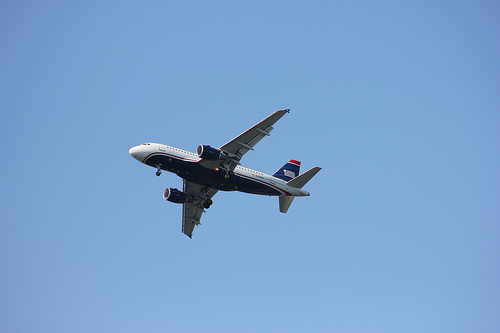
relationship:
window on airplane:
[147, 143, 151, 148] [125, 107, 324, 241]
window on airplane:
[142, 142, 146, 145] [125, 107, 324, 241]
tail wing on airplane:
[277, 193, 297, 214] [125, 107, 324, 241]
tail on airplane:
[285, 166, 325, 189] [125, 107, 324, 241]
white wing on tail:
[212, 103, 293, 163] [285, 166, 325, 189]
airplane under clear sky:
[125, 107, 324, 241] [2, 0, 497, 331]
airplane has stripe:
[125, 107, 324, 241] [156, 153, 276, 194]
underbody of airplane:
[148, 152, 282, 197] [125, 107, 324, 241]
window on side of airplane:
[162, 146, 176, 149] [125, 107, 324, 241]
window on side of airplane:
[254, 168, 264, 175] [125, 107, 324, 241]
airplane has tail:
[118, 102, 322, 242] [273, 152, 320, 217]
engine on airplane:
[163, 187, 200, 206] [125, 107, 324, 241]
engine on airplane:
[194, 141, 225, 162] [125, 107, 324, 241]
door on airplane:
[268, 175, 280, 188] [125, 107, 324, 241]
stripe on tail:
[284, 157, 302, 169] [273, 155, 301, 180]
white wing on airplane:
[212, 103, 293, 163] [118, 102, 322, 242]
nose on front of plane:
[122, 143, 150, 160] [119, 102, 325, 237]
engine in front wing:
[194, 141, 225, 162] [199, 107, 290, 173]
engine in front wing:
[163, 187, 200, 206] [182, 176, 210, 238]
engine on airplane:
[194, 141, 225, 162] [118, 102, 322, 242]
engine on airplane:
[163, 187, 200, 206] [118, 102, 322, 242]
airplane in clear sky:
[125, 107, 324, 241] [0, 0, 498, 331]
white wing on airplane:
[169, 177, 221, 241] [125, 107, 324, 241]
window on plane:
[162, 146, 176, 149] [102, 79, 359, 289]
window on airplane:
[261, 171, 264, 175] [125, 107, 324, 241]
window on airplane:
[253, 168, 255, 173] [125, 107, 324, 241]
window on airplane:
[239, 164, 244, 169] [125, 107, 324, 241]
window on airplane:
[177, 146, 182, 152] [125, 107, 324, 241]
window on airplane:
[239, 162, 246, 174] [125, 107, 324, 241]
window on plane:
[254, 168, 264, 175] [129, 102, 349, 230]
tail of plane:
[285, 166, 325, 189] [102, 79, 345, 248]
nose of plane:
[128, 144, 144, 159] [83, 95, 378, 215]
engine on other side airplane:
[161, 185, 198, 208] [125, 107, 324, 241]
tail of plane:
[262, 158, 324, 213] [84, 113, 359, 261]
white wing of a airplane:
[212, 103, 293, 163] [125, 107, 324, 241]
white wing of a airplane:
[212, 103, 293, 163] [91, 72, 376, 267]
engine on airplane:
[194, 141, 225, 162] [91, 72, 376, 267]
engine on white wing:
[194, 141, 225, 162] [212, 103, 293, 163]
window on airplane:
[186, 150, 191, 155] [125, 107, 324, 241]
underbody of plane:
[148, 152, 282, 197] [119, 102, 325, 237]